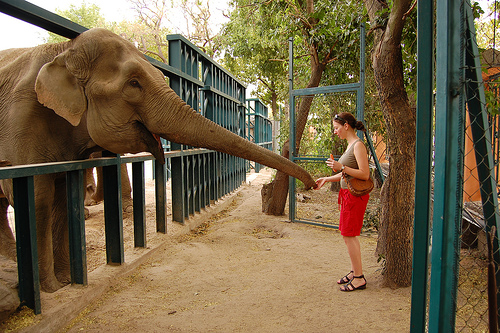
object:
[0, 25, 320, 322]
elephant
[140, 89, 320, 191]
trunk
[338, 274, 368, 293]
sandals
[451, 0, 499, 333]
fence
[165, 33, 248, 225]
bars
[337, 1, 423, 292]
trees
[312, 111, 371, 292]
woman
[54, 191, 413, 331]
ground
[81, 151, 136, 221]
elephant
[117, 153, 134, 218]
legs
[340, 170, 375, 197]
purse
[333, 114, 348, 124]
sunglasses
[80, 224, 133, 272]
dirt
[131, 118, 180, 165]
mouth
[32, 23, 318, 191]
head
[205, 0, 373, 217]
tree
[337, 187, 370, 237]
shorts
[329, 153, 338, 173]
carrot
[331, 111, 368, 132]
hair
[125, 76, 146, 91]
eye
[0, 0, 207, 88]
beam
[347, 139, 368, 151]
tank top